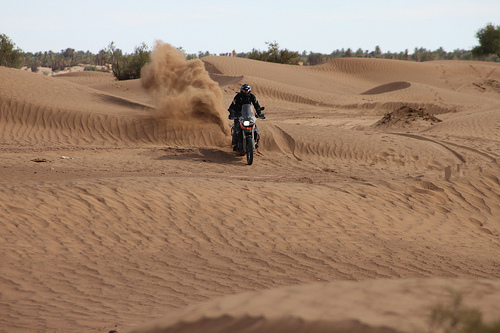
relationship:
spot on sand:
[356, 68, 410, 100] [2, 51, 499, 330]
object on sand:
[61, 154, 74, 162] [148, 220, 248, 300]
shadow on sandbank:
[146, 130, 243, 170] [280, 105, 471, 177]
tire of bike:
[240, 127, 254, 165] [234, 114, 257, 164]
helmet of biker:
[239, 80, 254, 97] [225, 81, 267, 121]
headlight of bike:
[243, 120, 250, 126] [227, 102, 267, 168]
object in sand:
[50, 143, 81, 170] [143, 174, 393, 314]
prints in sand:
[366, 122, 441, 222] [2, 51, 499, 330]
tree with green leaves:
[1, 32, 27, 69] [3, 37, 16, 63]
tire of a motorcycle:
[238, 115, 258, 169] [222, 97, 279, 175]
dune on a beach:
[0, 40, 496, 333] [191, 102, 443, 262]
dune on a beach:
[0, 40, 496, 333] [2, 57, 497, 328]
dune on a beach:
[272, 83, 462, 111] [2, 57, 497, 328]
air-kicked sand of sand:
[136, 38, 232, 144] [2, 51, 499, 330]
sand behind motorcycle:
[2, 51, 499, 330] [228, 99, 258, 163]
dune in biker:
[0, 40, 496, 333] [227, 83, 261, 150]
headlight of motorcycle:
[241, 118, 251, 127] [226, 104, 265, 164]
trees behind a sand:
[30, 33, 168, 89] [43, 174, 232, 257]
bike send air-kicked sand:
[230, 104, 260, 164] [136, 38, 232, 144]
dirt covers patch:
[126, 57, 301, 204] [12, 98, 497, 203]